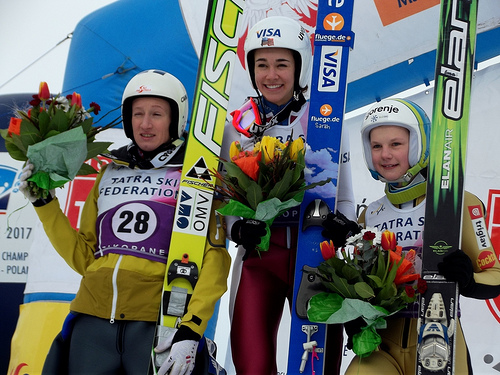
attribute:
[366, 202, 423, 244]
shirt — white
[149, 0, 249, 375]
ski — yellow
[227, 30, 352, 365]
women — posing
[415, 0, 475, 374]
ski — green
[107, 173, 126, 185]
letter — black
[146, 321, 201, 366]
glove — white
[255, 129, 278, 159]
flower — yellow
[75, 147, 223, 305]
jacket — yellow